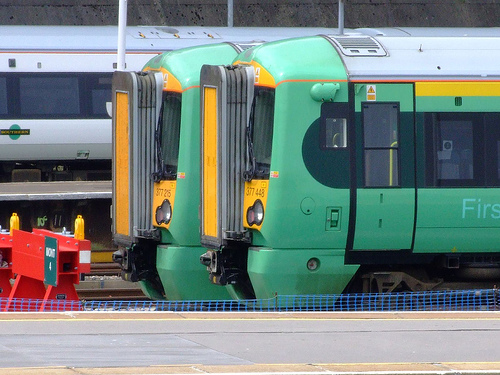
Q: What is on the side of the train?
A: A door.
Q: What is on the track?
A: A train.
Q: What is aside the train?
A: A blue net.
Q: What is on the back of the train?
A: A light.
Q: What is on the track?
A: Two green and yellow trains.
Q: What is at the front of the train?
A: A yellow and grey door.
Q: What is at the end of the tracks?
A: A red stop.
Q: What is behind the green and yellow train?
A: A white and grey train.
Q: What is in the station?
A: Three trains.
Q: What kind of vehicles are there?
A: Trains.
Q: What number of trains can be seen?
A: Three.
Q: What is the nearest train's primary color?
A: Green.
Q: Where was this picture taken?
A: A train yard.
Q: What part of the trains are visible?
A: The rear.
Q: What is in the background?
A: A train.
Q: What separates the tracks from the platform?
A: The blue net.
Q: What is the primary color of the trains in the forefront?
A: Green.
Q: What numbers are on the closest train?
A: 377448.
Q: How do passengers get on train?
A: The doors.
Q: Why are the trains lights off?
A: Train is not running.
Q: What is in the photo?
A: An aqua colored train.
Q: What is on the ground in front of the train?
A: A red device to stop a train.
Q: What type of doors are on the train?
A: Accordion doors.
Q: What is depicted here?
A: A door on a green train.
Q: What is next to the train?
A: An empty platform.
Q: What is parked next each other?
A: Trains that are visible.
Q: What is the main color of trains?
A: Green.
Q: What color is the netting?
A: Blue.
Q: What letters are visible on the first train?
A: First.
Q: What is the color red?
A: Item blocking train.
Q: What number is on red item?
A: 4.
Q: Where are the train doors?
A: Side of train.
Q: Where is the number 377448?
A: On first train.